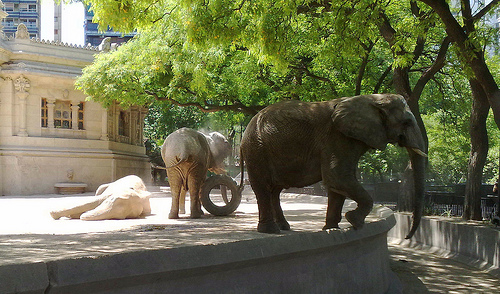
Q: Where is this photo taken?
A: At a zoo.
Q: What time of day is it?
A: Daytime.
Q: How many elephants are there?
A: Three.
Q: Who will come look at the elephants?
A: Tourists.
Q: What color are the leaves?
A: Green.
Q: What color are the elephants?
A: Gray.